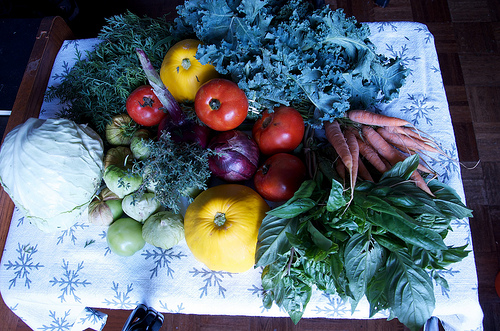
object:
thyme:
[53, 11, 176, 124]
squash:
[160, 39, 213, 101]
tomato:
[104, 213, 148, 256]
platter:
[9, 17, 472, 329]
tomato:
[126, 85, 164, 124]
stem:
[139, 99, 159, 110]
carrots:
[175, 0, 443, 203]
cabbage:
[0, 114, 105, 214]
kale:
[0, 113, 104, 215]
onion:
[205, 131, 258, 180]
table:
[0, 12, 485, 330]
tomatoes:
[125, 81, 308, 201]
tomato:
[87, 191, 123, 226]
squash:
[184, 184, 273, 276]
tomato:
[252, 110, 304, 150]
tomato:
[255, 153, 307, 201]